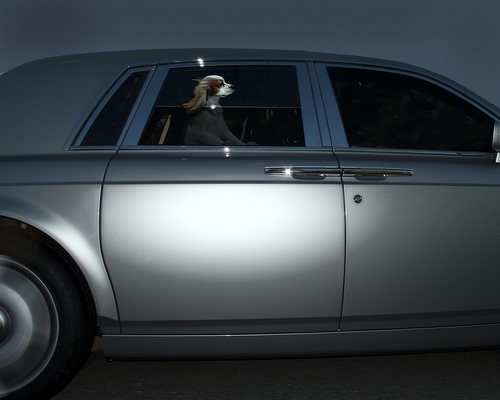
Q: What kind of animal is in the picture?
A: Dog.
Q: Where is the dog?
A: Window.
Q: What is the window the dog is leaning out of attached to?
A: Car.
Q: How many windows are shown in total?
A: Three.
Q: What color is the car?
A: Grey.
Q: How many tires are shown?
A: One.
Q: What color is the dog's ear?
A: Brown.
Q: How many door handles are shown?
A: Two.